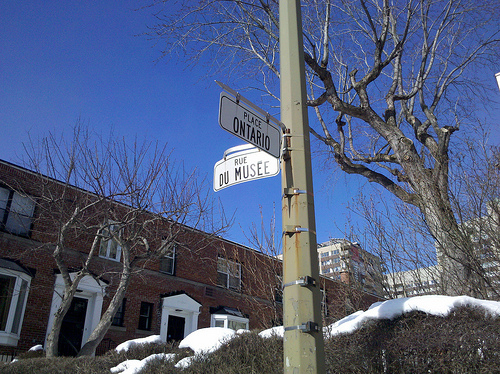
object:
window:
[214, 257, 242, 292]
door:
[44, 271, 110, 357]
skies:
[1, 0, 498, 270]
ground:
[373, 153, 381, 163]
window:
[160, 236, 176, 274]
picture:
[0, 0, 500, 374]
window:
[138, 300, 154, 330]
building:
[0, 160, 391, 372]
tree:
[127, 0, 499, 297]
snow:
[106, 292, 497, 372]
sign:
[218, 93, 281, 160]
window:
[331, 250, 338, 256]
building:
[317, 237, 386, 296]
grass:
[0, 303, 499, 374]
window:
[214, 253, 243, 291]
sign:
[213, 143, 281, 193]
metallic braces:
[280, 275, 318, 289]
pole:
[277, 0, 328, 374]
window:
[0, 187, 37, 237]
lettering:
[233, 116, 271, 150]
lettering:
[219, 160, 270, 186]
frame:
[79, 291, 104, 358]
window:
[0, 268, 32, 339]